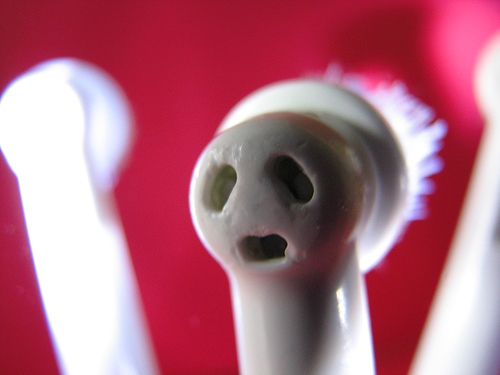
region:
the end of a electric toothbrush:
[182, 123, 370, 287]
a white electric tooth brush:
[190, 53, 442, 347]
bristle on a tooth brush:
[376, 98, 448, 228]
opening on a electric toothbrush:
[211, 141, 313, 278]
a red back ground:
[154, 29, 198, 161]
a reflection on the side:
[333, 271, 356, 346]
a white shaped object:
[1, 58, 143, 355]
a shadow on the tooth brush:
[236, 283, 396, 371]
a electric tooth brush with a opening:
[191, 110, 369, 343]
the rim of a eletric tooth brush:
[216, 64, 316, 139]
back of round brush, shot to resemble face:
[179, 51, 453, 373]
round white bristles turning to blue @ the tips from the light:
[313, 53, 450, 229]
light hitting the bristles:
[374, 101, 431, 210]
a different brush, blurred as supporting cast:
[0, 40, 185, 374]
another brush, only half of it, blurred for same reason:
[396, 27, 498, 374]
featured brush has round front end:
[180, 73, 415, 293]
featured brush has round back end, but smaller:
[185, 110, 367, 284]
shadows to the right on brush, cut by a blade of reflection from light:
[252, 90, 405, 374]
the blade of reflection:
[330, 283, 352, 334]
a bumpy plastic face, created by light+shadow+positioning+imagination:
[190, 135, 327, 277]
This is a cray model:
[146, 95, 404, 374]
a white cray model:
[186, 80, 392, 374]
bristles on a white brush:
[322, 60, 447, 218]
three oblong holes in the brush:
[200, 151, 315, 261]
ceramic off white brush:
[187, 78, 409, 373]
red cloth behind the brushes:
[1, 1, 493, 373]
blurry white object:
[1, 55, 161, 372]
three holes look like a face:
[206, 150, 316, 265]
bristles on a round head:
[213, 61, 445, 271]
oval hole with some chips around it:
[199, 145, 241, 217]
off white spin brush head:
[188, 62, 445, 369]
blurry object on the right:
[406, 33, 499, 371]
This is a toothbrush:
[131, 107, 384, 349]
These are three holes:
[225, 131, 290, 253]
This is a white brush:
[354, 76, 434, 181]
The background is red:
[98, 13, 243, 120]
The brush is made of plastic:
[184, 53, 362, 266]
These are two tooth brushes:
[42, 95, 229, 350]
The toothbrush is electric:
[155, 69, 372, 372]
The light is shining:
[110, 81, 405, 355]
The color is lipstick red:
[178, 70, 213, 86]